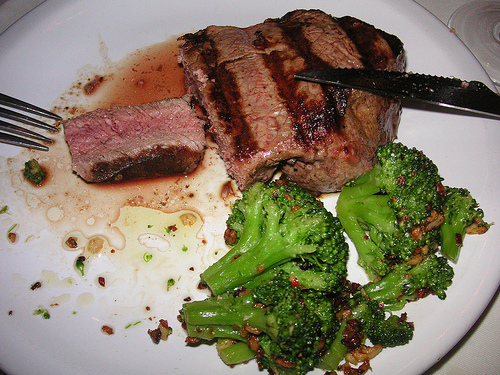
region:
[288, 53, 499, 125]
Jagged cutting knife with a sharp tip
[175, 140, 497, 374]
Pieces of cooked vegetable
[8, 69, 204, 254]
Soup remnants of the plate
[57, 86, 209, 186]
Cut out piece of barbecued meat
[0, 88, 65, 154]
Pointed tips of a fork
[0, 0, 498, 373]
Wide white plate with food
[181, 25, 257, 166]
Darkened portion of meat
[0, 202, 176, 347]
Pieces of scattered food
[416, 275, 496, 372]
Rim of a white plate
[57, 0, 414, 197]
Chunks of barbecued meat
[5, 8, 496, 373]
a white dinner plate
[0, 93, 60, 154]
a metal fork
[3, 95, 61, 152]
four tines of a metal fork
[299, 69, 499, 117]
the blade of a steak knife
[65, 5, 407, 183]
a piece of grilled steak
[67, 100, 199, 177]
a medium rare piece of steak cut off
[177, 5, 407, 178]
steak with grill marks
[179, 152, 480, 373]
a pile of steamed broccoli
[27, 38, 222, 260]
juices from the steak on the plate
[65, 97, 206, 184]
a rare piece of the steak on the left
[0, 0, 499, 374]
partially eaten meal on white plate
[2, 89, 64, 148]
top of silver fork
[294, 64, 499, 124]
top of silver knife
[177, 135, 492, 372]
bunch of green broccoli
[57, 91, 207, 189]
small piece of cut meat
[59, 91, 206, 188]
meat with pink in the middle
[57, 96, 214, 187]
meat cooked to medium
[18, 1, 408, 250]
blood and grease juice coming from meat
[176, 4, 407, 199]
piece of grilled meat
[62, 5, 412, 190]
almost half eaten steak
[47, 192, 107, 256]
Steak juice on top of plate.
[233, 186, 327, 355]
Stalk of celery on a plate.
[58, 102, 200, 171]
Small piece of steak on top of plate.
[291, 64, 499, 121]
Knife on top of piece of steak.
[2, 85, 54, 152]
Fork on top of plate.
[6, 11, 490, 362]
White plate on top of table.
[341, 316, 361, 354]
Brown piece of meat on top of broccoli.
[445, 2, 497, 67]
Bottom of a glass to the right.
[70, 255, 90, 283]
Small piece of broccoli on the plate.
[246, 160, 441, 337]
Four piece of broccoli together.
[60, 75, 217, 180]
sliced meat on plate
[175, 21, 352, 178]
char marks on meat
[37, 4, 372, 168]
meat is brown and pink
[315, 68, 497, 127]
steel knife on plate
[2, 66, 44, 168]
steel fork on plate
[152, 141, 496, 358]
green broccoli on plate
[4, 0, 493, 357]
plate is white and oval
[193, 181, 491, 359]
soy sauce on broccoli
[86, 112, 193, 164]
pink center to meat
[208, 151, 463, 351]
green vegetables on plate